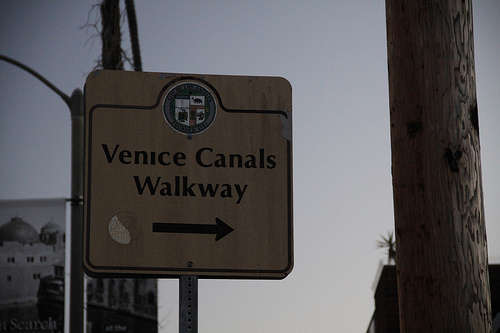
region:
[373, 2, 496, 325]
a wood utility pole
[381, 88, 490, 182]
dark spots on a pole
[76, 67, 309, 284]
a tan colored sign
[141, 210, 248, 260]
a black arrow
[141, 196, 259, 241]
an arrow pointing right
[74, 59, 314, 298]
sign says venice canals walkway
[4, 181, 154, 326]
a picture of a building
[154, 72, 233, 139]
a round seal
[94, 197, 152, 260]
a yin yang on a sign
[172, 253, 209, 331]
holes in a metal pole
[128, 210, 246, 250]
arrow giving direction to pedestrians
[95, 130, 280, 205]
sign written in English in a country speaking a different language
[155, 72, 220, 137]
insignia composed of different designs and colors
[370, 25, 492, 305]
pole marked with intricate patterns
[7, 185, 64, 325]
banner printed with historic buildings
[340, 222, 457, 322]
corner of building with plant on top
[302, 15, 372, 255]
gray sky in different hues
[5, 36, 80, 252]
tall post with extension reaching out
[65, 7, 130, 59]
tree with short bare twigs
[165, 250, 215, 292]
metal bolt holding sign onto pole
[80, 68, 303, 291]
A brown sign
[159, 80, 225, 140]
An emblem on the sign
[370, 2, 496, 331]
A tree next to the sign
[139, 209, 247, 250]
A black arrow on the sign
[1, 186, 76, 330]
A banner in the background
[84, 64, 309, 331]
The sign is on a post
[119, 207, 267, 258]
The arrow is pointing to the right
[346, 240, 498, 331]
There is a building in the background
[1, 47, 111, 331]
There is a light pole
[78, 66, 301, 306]
The sign has black lettering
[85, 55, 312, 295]
a sign pointing to the "Venice Canals Walkway"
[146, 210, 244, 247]
a black arrow on the sign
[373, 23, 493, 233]
a wood utility pole next to the sign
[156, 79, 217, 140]
the city seal on the sign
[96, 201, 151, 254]
a design next to the arrow on the sign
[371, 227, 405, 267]
a palm tree on top of a building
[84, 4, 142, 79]
a tree with branches behind the sign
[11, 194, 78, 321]
a flag on a lightpost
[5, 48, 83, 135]
the top curved bar of a lamp post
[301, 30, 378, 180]
the clear sky behind the sign